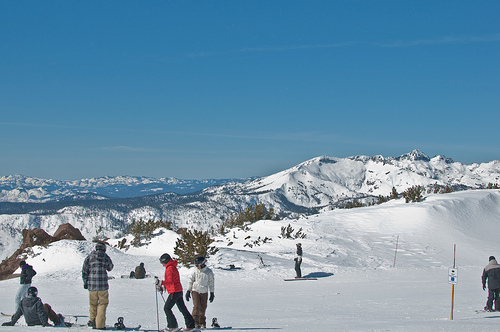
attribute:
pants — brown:
[188, 290, 209, 330]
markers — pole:
[445, 240, 472, 329]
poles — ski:
[152, 279, 170, 325]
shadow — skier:
[298, 261, 333, 282]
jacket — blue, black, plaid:
[81, 249, 115, 291]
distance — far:
[10, 169, 131, 193]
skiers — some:
[20, 267, 212, 324]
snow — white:
[251, 291, 290, 307]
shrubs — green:
[233, 208, 271, 221]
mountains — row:
[31, 170, 292, 199]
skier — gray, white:
[478, 254, 497, 311]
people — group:
[7, 237, 497, 325]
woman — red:
[154, 251, 188, 329]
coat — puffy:
[160, 260, 183, 291]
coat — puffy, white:
[184, 267, 218, 297]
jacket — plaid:
[83, 249, 113, 289]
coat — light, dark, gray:
[483, 265, 497, 283]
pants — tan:
[81, 289, 132, 329]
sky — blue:
[20, 9, 472, 191]